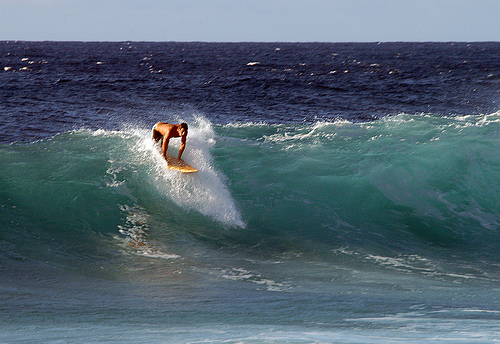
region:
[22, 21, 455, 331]
This is in the ocean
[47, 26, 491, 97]
The ocean is black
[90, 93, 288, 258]
This man is surfing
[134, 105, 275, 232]
The wave here is white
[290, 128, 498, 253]
The water here is turqoise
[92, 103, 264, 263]
The man is about to stand up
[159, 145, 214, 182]
This surfboard is yellow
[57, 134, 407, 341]
This wave is big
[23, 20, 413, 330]
This is along a coast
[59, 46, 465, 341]
This is near a beach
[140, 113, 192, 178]
surfing attempting to stand on board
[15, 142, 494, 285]
swell of wave surfer is on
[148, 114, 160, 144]
swim trunks of surfer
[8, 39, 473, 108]
ripples in ocean water behind wave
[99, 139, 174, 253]
white spray creating by surfboard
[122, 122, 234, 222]
white foam around surfboard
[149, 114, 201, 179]
man with all fours on surfboard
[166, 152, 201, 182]
tip of surfboard on wave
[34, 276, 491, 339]
calm waters in front of wave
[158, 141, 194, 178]
surfboard man is riding on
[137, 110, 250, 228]
man surfing in the water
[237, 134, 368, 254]
aqua colored water of the ocean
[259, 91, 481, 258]
large blue and green wave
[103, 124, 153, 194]
white water slashing in the ocean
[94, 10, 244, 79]
sky and water horizan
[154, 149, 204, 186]
yellow surfing board on the water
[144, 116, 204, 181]
man bending down on a surf board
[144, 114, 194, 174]
man with white swimming shorts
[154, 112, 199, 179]
man with tanned skin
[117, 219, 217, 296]
surfer reflection in the water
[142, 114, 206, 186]
a surfer in a wave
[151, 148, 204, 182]
a yellow surfboard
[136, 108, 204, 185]
man is on yellow surfboard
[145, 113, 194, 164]
man wears shorts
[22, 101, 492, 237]
a wave rolling in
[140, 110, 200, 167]
both hands of man on surfboard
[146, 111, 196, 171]
man is kneeling on a surfboard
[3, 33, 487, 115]
part of the ocean is blue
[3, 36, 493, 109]
water of the ocean is calm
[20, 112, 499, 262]
a high wave in the ocean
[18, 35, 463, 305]
A person is riding a surfboard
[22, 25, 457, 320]
A person is riding a wave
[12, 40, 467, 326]
A person is in the ocean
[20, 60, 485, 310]
A person is at a beach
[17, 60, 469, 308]
The man is on vacation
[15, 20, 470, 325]
The man is enjoying surfing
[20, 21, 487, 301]
The man is on top of a wave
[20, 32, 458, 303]
The man is getting wet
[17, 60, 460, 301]
The man is a good swimmer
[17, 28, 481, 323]
The wave is coming into shore